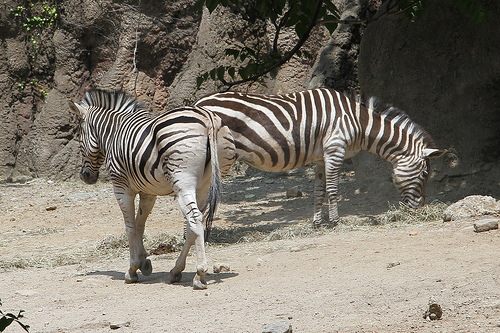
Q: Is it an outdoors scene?
A: Yes, it is outdoors.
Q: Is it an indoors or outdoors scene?
A: It is outdoors.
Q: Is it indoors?
A: No, it is outdoors.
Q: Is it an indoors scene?
A: No, it is outdoors.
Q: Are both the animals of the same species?
A: Yes, all the animals are zebras.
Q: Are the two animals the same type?
A: Yes, all the animals are zebras.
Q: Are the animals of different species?
A: No, all the animals are zebras.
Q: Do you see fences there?
A: No, there are no fences.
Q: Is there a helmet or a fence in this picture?
A: No, there are no fences or helmets.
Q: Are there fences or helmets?
A: No, there are no fences or helmets.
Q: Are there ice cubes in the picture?
A: No, there are no ice cubes.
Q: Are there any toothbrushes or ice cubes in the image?
A: No, there are no ice cubes or toothbrushes.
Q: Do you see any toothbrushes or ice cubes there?
A: No, there are no ice cubes or toothbrushes.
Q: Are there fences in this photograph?
A: No, there are no fences.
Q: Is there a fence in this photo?
A: No, there are no fences.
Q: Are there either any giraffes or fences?
A: No, there are no fences or giraffes.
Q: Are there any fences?
A: No, there are no fences.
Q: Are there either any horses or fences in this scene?
A: No, there are no fences or horses.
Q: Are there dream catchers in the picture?
A: No, there are no dream catchers.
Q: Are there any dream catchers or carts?
A: No, there are no dream catchers or carts.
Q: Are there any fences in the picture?
A: No, there are no fences.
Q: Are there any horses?
A: No, there are no horses.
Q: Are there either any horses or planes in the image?
A: No, there are no horses or planes.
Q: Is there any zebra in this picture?
A: Yes, there is a zebra.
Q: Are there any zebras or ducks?
A: Yes, there is a zebra.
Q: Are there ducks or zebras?
A: Yes, there is a zebra.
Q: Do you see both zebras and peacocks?
A: No, there is a zebra but no peacocks.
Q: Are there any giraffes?
A: No, there are no giraffes.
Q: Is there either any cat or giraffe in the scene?
A: No, there are no giraffes or cats.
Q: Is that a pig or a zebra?
A: That is a zebra.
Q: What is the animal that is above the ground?
A: The animal is a zebra.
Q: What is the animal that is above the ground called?
A: The animal is a zebra.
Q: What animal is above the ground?
A: The animal is a zebra.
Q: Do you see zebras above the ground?
A: Yes, there is a zebra above the ground.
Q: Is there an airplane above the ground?
A: No, there is a zebra above the ground.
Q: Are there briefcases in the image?
A: No, there are no briefcases.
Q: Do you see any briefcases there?
A: No, there are no briefcases.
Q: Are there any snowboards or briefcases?
A: No, there are no briefcases or snowboards.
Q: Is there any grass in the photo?
A: Yes, there is grass.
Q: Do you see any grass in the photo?
A: Yes, there is grass.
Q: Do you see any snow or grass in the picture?
A: Yes, there is grass.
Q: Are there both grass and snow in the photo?
A: No, there is grass but no snow.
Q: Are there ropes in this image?
A: No, there are no ropes.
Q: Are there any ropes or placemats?
A: No, there are no ropes or placemats.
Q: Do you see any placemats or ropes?
A: No, there are no ropes or placemats.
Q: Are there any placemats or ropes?
A: No, there are no ropes or placemats.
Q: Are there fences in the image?
A: No, there are no fences.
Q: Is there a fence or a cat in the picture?
A: No, there are no fences or cats.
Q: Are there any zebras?
A: Yes, there is a zebra.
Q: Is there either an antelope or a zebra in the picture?
A: Yes, there is a zebra.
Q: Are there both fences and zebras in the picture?
A: No, there is a zebra but no fences.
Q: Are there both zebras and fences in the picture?
A: No, there is a zebra but no fences.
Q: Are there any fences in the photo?
A: No, there are no fences.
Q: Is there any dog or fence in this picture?
A: No, there are no fences or dogs.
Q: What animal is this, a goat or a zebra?
A: This is a zebra.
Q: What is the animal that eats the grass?
A: The animal is a zebra.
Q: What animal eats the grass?
A: The animal is a zebra.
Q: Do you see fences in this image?
A: No, there are no fences.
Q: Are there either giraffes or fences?
A: No, there are no fences or giraffes.